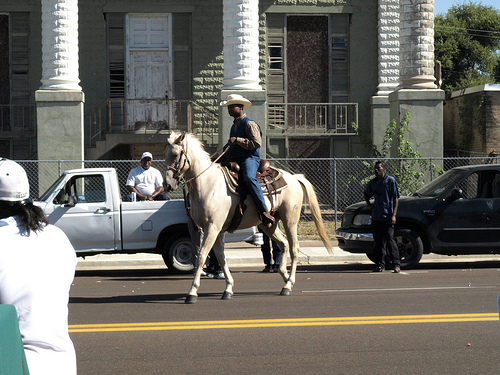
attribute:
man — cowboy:
[215, 89, 279, 230]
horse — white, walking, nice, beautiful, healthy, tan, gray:
[158, 124, 335, 305]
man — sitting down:
[124, 146, 168, 203]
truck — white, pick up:
[28, 164, 267, 277]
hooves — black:
[183, 287, 295, 304]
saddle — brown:
[221, 159, 287, 234]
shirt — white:
[125, 162, 165, 195]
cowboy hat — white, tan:
[217, 93, 252, 106]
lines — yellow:
[69, 308, 500, 335]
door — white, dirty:
[123, 12, 179, 126]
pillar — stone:
[398, 1, 437, 89]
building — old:
[1, 1, 446, 207]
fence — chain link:
[18, 160, 499, 245]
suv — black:
[332, 161, 499, 273]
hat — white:
[138, 149, 157, 161]